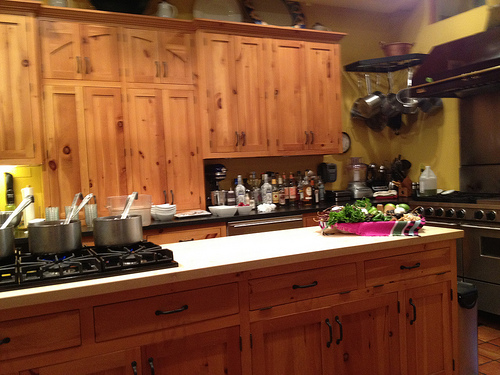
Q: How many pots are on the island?
A: Three.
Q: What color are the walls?
A: Yellow.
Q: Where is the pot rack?
A: In the corner.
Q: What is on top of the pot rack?
A: A copper pot.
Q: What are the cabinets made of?
A: Wood.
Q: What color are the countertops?
A: Black and white.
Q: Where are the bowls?
A: On the countertop.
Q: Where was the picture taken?
A: In a kitchen.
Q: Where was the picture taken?
A: The kitchen.